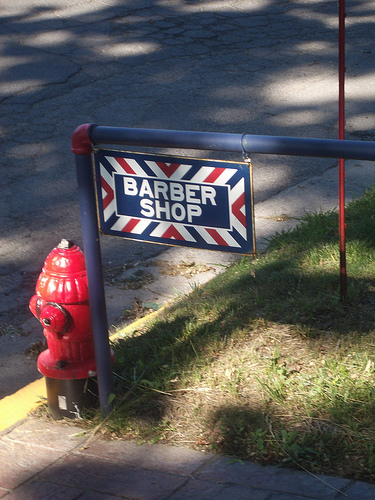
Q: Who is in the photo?
A: Nobody.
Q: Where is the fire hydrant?
A: Next to the pole.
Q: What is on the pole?
A: A barber shop sign.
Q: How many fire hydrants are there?
A: One.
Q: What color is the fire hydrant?
A: Red.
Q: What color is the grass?
A: Green.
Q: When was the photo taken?
A: During the day.